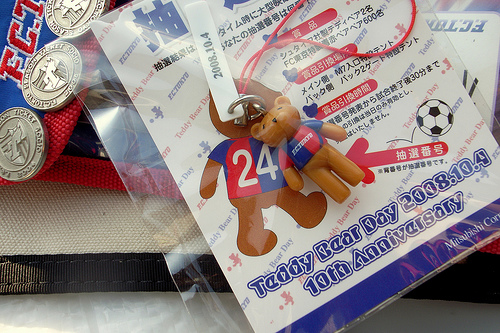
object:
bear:
[243, 95, 364, 204]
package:
[48, 0, 500, 314]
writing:
[298, 40, 441, 140]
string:
[236, 0, 413, 93]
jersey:
[274, 119, 323, 171]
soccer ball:
[413, 98, 452, 137]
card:
[80, 1, 498, 332]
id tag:
[180, 1, 248, 124]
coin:
[1, 105, 47, 182]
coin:
[17, 42, 91, 111]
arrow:
[342, 135, 450, 184]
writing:
[243, 145, 495, 307]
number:
[225, 146, 279, 189]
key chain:
[228, 92, 266, 125]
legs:
[308, 161, 351, 205]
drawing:
[189, 77, 331, 259]